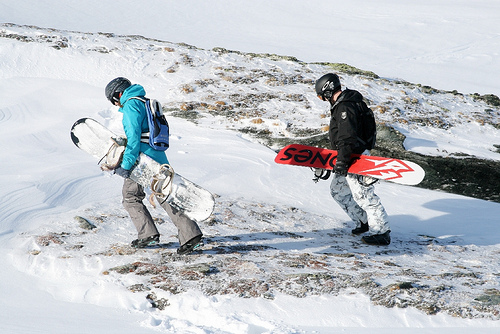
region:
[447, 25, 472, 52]
white clouds in blue sky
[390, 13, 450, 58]
white clouds in blue sky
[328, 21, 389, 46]
white clouds in blue sky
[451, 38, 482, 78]
white clouds in blue sky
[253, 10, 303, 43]
white clouds in blue sky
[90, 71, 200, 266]
man with snow board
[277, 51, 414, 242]
man with snow board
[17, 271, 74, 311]
white snow on hill side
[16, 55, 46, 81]
white snow on hill side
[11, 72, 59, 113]
white snow on hill side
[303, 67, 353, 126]
the head of a man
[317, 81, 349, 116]
the neck of a man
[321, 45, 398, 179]
the arm of a man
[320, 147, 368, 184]
the hand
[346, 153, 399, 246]
the leg of a man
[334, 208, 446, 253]
the feet of a man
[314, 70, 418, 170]
a man wearing a coat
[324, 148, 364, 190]
a man wearing a glove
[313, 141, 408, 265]
a man wearing pants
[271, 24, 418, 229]
a man in the snow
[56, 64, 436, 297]
two people walking on snow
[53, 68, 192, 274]
a person walking on snow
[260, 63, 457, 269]
a person carrying a snowboard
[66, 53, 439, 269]
two people carrying snowboards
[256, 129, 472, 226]
a red and white snowboard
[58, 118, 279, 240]
a snowboard with snow on it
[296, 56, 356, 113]
someone wearing a black helmet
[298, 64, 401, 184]
someone wearing a black ski jacket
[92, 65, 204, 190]
someone wearing a backpack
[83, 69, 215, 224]
someone wearing a blue ski jacket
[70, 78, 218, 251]
A man holding a snowboard.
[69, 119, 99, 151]
Part of the snowboard.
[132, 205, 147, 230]
Part of the man's pants.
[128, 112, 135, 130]
Part of the man's blue jacket.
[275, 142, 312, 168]
Part of the snowboard.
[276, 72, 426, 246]
A man holding a snowboard.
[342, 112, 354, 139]
Part of the man's jacket.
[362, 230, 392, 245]
The man's black shoe.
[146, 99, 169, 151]
A blue backpack.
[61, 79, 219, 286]
man with snow board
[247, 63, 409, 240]
man with snow board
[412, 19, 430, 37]
white clouds in blue sky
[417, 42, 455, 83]
white clouds in blue sky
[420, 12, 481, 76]
white clouds in blue sky